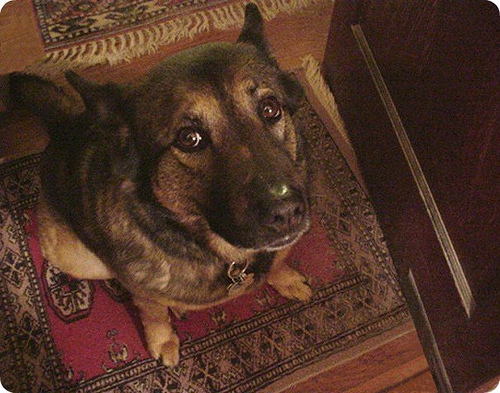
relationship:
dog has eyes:
[4, 2, 359, 372] [154, 94, 293, 150]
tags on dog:
[218, 255, 263, 300] [4, 2, 359, 372]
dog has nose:
[4, 2, 359, 372] [256, 185, 307, 233]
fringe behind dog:
[32, 2, 314, 62] [4, 2, 359, 372]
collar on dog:
[161, 217, 250, 269] [4, 2, 359, 372]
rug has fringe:
[30, 1, 324, 61] [32, 2, 314, 62]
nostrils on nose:
[263, 203, 303, 223] [256, 185, 307, 233]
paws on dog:
[123, 263, 320, 382] [4, 2, 359, 372]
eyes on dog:
[154, 94, 293, 150] [4, 2, 359, 372]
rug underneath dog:
[2, 66, 440, 393] [4, 2, 359, 372]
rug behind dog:
[30, 1, 324, 61] [4, 2, 359, 372]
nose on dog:
[256, 185, 307, 233] [4, 2, 359, 372]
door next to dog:
[324, 1, 496, 385] [4, 2, 359, 372]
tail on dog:
[5, 63, 91, 140] [4, 2, 359, 372]